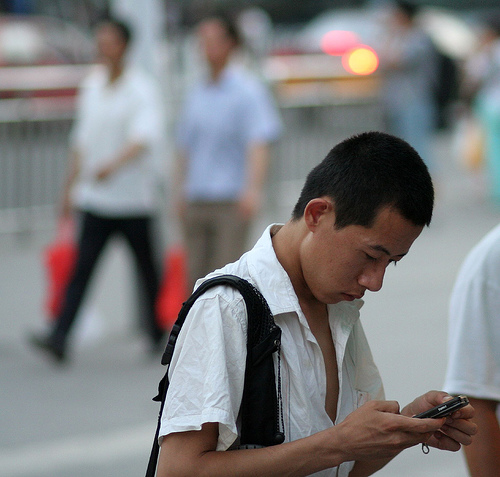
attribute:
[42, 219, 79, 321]
red bag — large 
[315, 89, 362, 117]
rod — metal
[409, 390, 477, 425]
cellphone — black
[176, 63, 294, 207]
shirt — blue